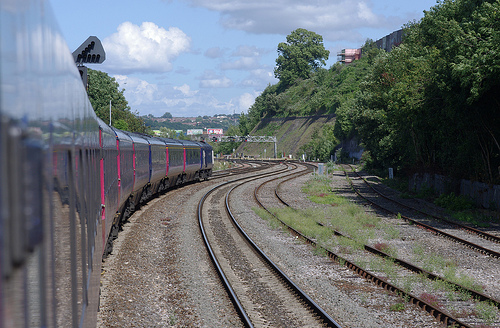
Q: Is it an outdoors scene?
A: Yes, it is outdoors.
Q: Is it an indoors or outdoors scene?
A: It is outdoors.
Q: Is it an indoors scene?
A: No, it is outdoors.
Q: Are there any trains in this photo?
A: Yes, there is a train.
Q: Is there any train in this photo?
A: Yes, there is a train.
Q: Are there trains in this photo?
A: Yes, there is a train.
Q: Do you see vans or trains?
A: Yes, there is a train.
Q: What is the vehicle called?
A: The vehicle is a train.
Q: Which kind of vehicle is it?
A: The vehicle is a train.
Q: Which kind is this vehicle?
A: This is a train.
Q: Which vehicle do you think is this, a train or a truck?
A: This is a train.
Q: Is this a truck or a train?
A: This is a train.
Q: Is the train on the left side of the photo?
A: Yes, the train is on the left of the image.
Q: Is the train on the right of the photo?
A: No, the train is on the left of the image.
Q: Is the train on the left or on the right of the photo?
A: The train is on the left of the image.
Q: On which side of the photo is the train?
A: The train is on the left of the image.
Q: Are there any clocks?
A: No, there are no clocks.